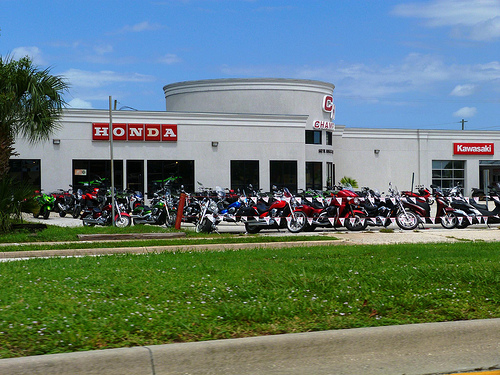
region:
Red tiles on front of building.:
[88, 108, 274, 193]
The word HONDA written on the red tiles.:
[89, 110, 233, 189]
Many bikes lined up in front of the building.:
[109, 187, 459, 227]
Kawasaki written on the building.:
[450, 126, 498, 172]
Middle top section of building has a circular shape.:
[147, 69, 383, 152]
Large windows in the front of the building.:
[38, 137, 346, 213]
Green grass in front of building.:
[123, 257, 438, 362]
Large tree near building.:
[8, 53, 91, 198]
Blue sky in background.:
[171, 33, 393, 76]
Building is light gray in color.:
[117, 70, 399, 227]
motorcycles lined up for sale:
[5, 173, 497, 229]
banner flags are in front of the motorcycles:
[232, 190, 497, 230]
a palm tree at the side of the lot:
[0, 57, 66, 250]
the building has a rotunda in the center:
[18, 75, 490, 222]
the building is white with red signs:
[8, 75, 495, 230]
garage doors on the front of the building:
[427, 155, 497, 216]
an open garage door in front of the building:
[475, 156, 496, 208]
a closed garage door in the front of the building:
[428, 155, 468, 208]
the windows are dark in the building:
[67, 126, 337, 218]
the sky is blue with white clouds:
[7, 2, 497, 149]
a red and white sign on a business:
[96, 116, 193, 146]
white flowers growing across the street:
[89, 267, 136, 308]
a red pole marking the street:
[166, 188, 187, 223]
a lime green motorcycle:
[31, 194, 60, 219]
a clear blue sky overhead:
[224, 9, 333, 55]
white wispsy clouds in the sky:
[351, 57, 438, 98]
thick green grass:
[316, 249, 386, 263]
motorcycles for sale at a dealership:
[263, 185, 472, 222]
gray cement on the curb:
[270, 338, 412, 368]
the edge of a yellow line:
[464, 368, 497, 373]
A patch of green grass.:
[0, 238, 496, 356]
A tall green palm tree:
[0, 45, 70, 230]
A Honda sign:
[85, 120, 176, 140]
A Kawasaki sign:
[450, 140, 496, 160]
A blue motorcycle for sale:
[192, 185, 262, 230]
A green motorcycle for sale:
[25, 190, 55, 215]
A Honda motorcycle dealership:
[2, 75, 493, 230]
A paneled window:
[427, 156, 464, 191]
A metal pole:
[102, 95, 117, 235]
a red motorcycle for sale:
[315, 182, 370, 228]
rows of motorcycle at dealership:
[69, 94, 497, 237]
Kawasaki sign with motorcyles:
[409, 124, 496, 241]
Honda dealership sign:
[84, 114, 193, 176]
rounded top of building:
[128, 31, 346, 113]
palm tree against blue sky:
[3, 38, 74, 106]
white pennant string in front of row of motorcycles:
[230, 182, 469, 232]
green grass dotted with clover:
[107, 293, 250, 332]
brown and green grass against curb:
[188, 312, 405, 369]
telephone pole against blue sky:
[438, 104, 481, 130]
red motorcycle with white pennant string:
[243, 186, 314, 236]